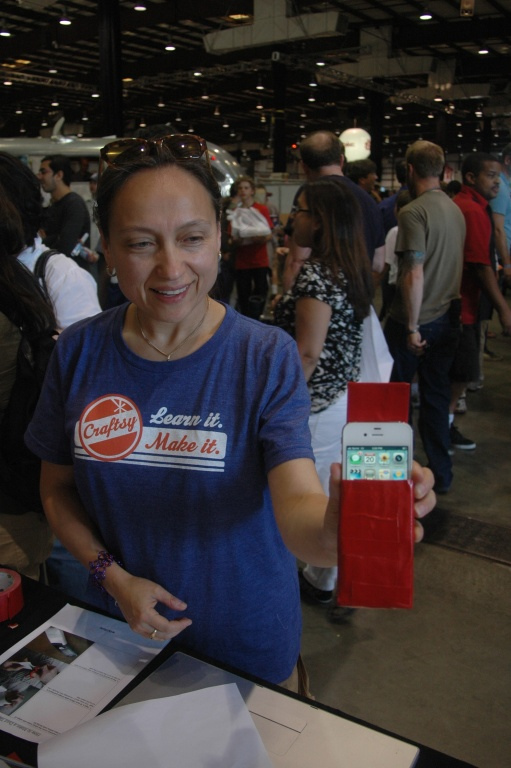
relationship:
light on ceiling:
[162, 45, 173, 53] [0, 3, 508, 176]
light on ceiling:
[134, 6, 144, 12] [0, 3, 508, 176]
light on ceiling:
[419, 15, 433, 21] [0, 3, 508, 176]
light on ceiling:
[476, 50, 488, 55] [0, 3, 508, 176]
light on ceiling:
[474, 110, 482, 118] [0, 3, 508, 176]